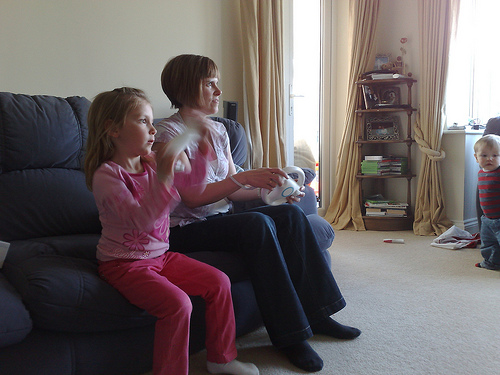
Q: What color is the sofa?
A: Blue.